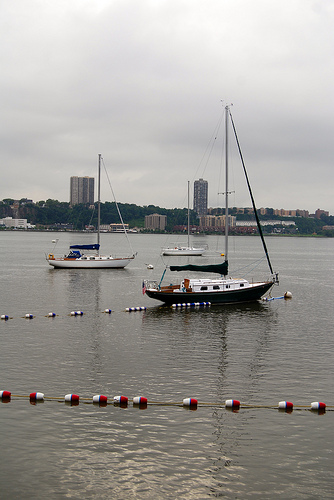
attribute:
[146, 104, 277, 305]
boat — white, floating, black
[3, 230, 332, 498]
water — calm, big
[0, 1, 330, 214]
sky — blue, overcast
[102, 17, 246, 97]
cloud — white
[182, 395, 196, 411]
buoy — red, white, on string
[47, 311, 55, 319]
buoy — blue, white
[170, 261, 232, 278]
sail — black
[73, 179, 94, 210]
building — tall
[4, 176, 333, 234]
skyline — of the city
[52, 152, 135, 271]
boat — white